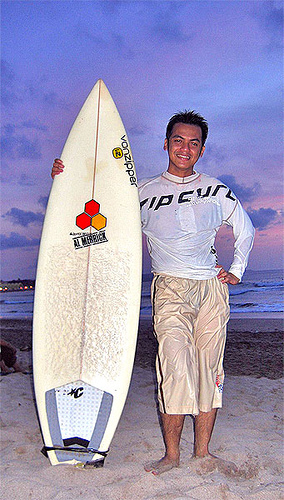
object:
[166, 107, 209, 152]
brown hair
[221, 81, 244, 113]
wall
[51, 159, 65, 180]
fingers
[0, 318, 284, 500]
beach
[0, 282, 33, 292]
homes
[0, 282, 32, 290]
buildings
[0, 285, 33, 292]
lights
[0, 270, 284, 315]
ocean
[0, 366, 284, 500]
sand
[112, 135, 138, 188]
logo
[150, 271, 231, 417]
shorts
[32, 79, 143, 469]
board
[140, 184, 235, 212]
logo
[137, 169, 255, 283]
shirt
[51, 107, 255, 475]
man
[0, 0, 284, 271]
clouds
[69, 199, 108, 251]
logo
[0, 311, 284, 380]
shore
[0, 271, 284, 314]
wave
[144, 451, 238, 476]
feet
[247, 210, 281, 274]
sunset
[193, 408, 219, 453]
leg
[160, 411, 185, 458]
leg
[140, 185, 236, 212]
black lettering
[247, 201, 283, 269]
pink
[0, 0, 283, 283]
sky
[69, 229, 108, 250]
text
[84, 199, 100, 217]
hexagon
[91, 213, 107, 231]
hexagon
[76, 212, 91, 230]
hexagon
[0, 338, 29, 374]
person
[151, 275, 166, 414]
stripe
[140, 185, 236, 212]
text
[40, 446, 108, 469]
ankle strap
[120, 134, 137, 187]
von zipper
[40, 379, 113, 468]
surfboard rudder